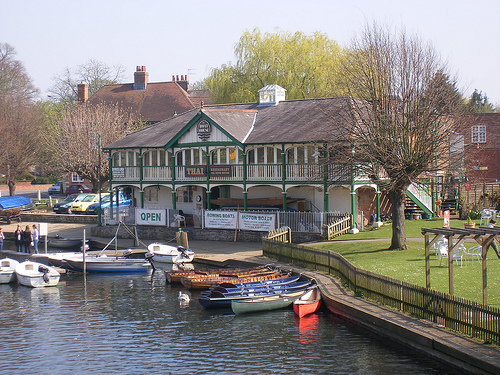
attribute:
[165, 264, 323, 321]
boats — tied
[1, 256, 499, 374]
water — calm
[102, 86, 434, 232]
building — green, white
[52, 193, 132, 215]
cars — parked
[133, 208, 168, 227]
sign — white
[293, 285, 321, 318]
boat — red, white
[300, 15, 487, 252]
tree — leafless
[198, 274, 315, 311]
boats — blue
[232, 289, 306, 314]
canoe — light green, red, green, white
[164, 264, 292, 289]
boats — brown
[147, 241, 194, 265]
motorboat — white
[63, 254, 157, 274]
motoboat — silver, blue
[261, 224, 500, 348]
fence — short, wooden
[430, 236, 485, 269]
chairs — white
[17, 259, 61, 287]
boat — tied